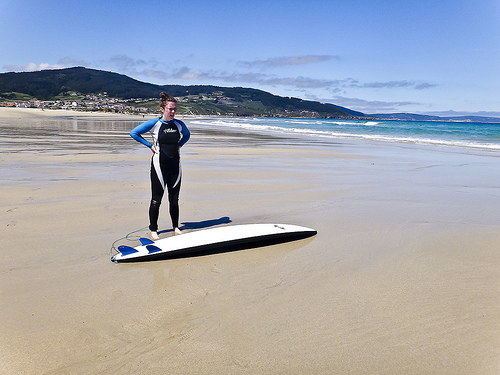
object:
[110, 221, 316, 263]
board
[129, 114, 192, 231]
wetsuit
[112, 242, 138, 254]
fins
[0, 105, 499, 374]
beach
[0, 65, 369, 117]
mountains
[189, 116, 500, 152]
waves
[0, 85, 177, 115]
village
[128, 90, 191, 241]
woman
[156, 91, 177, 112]
hair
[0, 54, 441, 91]
clouds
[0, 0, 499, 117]
sky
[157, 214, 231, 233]
shadow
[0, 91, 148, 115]
buildings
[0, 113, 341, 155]
water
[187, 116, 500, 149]
water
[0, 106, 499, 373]
sand